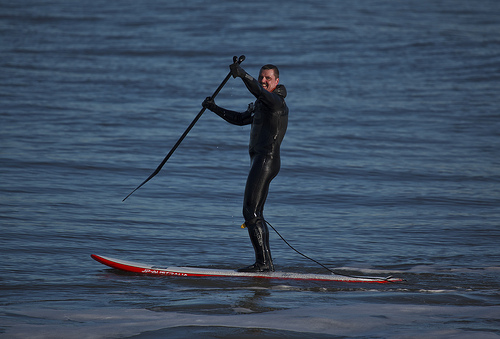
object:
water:
[3, 5, 500, 333]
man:
[206, 44, 305, 271]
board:
[88, 247, 408, 288]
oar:
[115, 49, 250, 205]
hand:
[222, 47, 247, 81]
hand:
[200, 92, 217, 114]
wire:
[260, 213, 399, 281]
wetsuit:
[219, 81, 290, 271]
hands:
[203, 57, 246, 113]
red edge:
[97, 264, 403, 284]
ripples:
[27, 28, 205, 79]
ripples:
[345, 33, 461, 87]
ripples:
[340, 120, 473, 216]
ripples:
[32, 167, 117, 229]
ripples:
[225, 7, 367, 65]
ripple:
[320, 262, 496, 300]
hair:
[262, 63, 282, 76]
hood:
[274, 83, 290, 98]